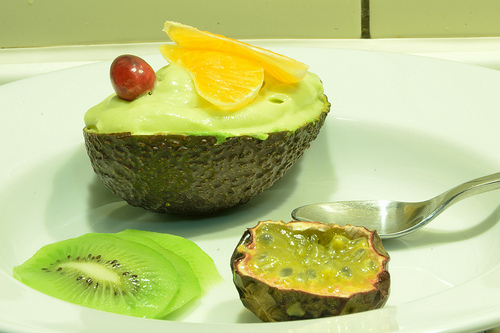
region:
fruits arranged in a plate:
[15, 43, 480, 319]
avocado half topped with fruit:
[85, 40, 340, 211]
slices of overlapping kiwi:
[6, 225, 216, 325]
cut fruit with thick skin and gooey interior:
[227, 216, 397, 316]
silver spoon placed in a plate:
[286, 120, 496, 255]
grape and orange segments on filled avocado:
[102, 15, 327, 115]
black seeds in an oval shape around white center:
[36, 250, 151, 301]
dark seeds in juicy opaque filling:
[230, 220, 400, 300]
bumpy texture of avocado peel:
[105, 145, 265, 200]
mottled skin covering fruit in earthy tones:
[225, 270, 355, 315]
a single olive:
[110, 47, 157, 102]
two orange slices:
[158, 16, 312, 109]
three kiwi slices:
[8, 218, 221, 322]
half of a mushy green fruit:
[226, 212, 394, 317]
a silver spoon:
[293, 170, 499, 237]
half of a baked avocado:
[83, 50, 333, 218]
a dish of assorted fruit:
[0, 41, 499, 330]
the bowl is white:
[1, 43, 498, 331]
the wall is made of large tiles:
[1, 1, 498, 36]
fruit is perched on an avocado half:
[83, 17, 333, 216]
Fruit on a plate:
[34, 27, 389, 324]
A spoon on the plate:
[288, 154, 498, 229]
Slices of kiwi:
[7, 215, 219, 320]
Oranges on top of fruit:
[159, 12, 305, 108]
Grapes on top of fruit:
[105, 48, 162, 105]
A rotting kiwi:
[231, 215, 391, 327]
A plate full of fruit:
[4, 48, 494, 332]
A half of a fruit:
[79, 94, 326, 212]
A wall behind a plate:
[1, 0, 497, 38]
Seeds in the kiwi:
[46, 251, 150, 299]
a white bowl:
[4, 41, 498, 330]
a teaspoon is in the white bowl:
[289, 170, 499, 235]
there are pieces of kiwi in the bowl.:
[13, 225, 218, 320]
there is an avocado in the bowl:
[81, 15, 333, 213]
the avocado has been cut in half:
[81, 18, 328, 211]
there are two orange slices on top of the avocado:
[152, 19, 304, 101]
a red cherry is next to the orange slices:
[108, 52, 160, 97]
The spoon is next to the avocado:
[78, 25, 496, 235]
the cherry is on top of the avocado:
[107, 50, 160, 101]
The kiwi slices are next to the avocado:
[14, 222, 216, 332]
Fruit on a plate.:
[5, 23, 495, 329]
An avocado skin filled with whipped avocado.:
[66, 1, 337, 211]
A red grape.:
[105, 50, 157, 105]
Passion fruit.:
[230, 215, 395, 307]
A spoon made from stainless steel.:
[287, 150, 497, 260]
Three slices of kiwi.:
[12, 220, 212, 315]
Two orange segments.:
[160, 16, 302, 106]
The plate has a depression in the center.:
[12, 105, 494, 321]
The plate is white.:
[5, 57, 495, 322]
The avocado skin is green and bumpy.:
[80, 123, 295, 213]